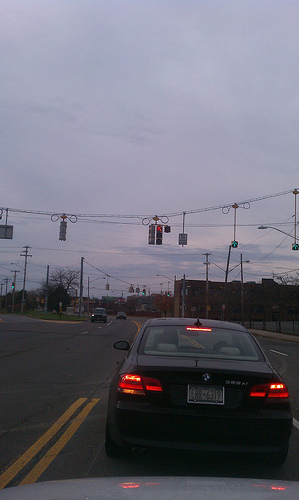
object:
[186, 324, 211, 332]
light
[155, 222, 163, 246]
light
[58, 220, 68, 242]
light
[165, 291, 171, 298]
light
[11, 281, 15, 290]
light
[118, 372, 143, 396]
light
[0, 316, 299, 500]
ground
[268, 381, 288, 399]
tail light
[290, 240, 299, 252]
traffic signal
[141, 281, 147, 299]
traffic signal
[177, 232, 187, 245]
sign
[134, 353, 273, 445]
trunk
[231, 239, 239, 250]
traffic signal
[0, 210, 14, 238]
signal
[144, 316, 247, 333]
roof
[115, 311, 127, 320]
car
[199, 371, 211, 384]
bmw logo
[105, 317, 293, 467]
car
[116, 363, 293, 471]
rear end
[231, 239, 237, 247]
arrow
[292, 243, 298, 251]
arrow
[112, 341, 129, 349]
mirror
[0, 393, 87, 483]
lines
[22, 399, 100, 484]
lines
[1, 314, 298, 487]
street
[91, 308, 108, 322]
car front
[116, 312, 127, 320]
car front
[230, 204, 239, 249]
signal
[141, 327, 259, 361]
window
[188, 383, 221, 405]
license plate